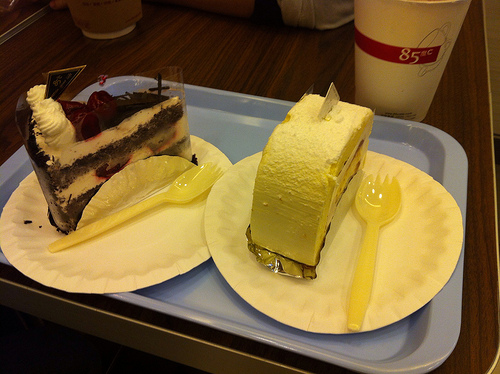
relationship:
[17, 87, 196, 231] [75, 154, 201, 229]
cake on top of paper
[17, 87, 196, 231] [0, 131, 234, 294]
cake on top of plate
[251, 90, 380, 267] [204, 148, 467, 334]
cake on top of plate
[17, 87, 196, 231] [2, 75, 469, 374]
cake on top of tray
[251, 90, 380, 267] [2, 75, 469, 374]
cake on top of tray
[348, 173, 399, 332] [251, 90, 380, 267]
utensil next to cake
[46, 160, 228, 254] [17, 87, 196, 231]
utensil next to cake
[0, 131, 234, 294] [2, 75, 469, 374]
plate on top of tray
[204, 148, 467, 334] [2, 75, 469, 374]
plate on top of tray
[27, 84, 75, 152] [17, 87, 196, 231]
topping on top of cake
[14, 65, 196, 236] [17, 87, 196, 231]
wrapper surrounding cake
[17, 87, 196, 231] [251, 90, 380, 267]
cake next to cake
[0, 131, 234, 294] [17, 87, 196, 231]
plate under cake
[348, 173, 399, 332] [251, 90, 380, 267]
utensil beside cake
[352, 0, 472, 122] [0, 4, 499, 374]
cup on top of table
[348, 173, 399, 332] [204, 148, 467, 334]
utensil on top of plate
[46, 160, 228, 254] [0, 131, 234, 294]
utensil on top of plate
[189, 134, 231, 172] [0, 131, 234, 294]
edge of plate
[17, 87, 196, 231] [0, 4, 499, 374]
cake on top of table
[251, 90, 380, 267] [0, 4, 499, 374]
cake on top of table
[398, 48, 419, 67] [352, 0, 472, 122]
number printed on cup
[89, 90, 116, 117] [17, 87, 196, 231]
cherry on top of cake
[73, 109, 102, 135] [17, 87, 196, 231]
cherry on top of cake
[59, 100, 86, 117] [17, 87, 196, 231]
cherry on top of cake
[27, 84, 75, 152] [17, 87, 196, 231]
topping piped on top of cake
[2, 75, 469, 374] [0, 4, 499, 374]
tray on top of table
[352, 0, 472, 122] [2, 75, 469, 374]
cup next to tray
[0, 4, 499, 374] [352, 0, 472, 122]
table under cup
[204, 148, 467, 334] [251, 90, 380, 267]
plate under cake